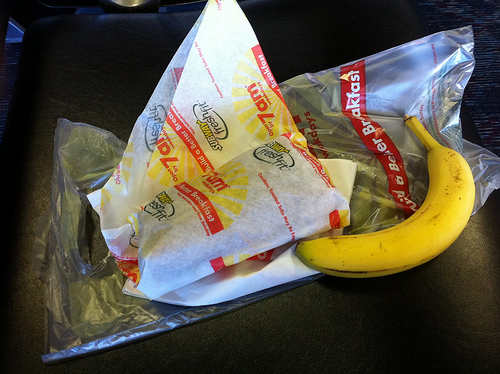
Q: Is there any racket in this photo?
A: No, there are no rackets.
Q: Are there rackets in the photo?
A: No, there are no rackets.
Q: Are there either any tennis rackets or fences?
A: No, there are no tennis rackets or fences.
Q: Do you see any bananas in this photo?
A: Yes, there is a banana.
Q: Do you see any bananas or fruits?
A: Yes, there is a banana.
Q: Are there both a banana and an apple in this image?
A: No, there is a banana but no apples.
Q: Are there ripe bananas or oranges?
A: Yes, there is a ripe banana.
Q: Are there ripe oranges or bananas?
A: Yes, there is a ripe banana.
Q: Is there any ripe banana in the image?
A: Yes, there is a ripe banana.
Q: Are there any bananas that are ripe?
A: Yes, there is a banana that is ripe.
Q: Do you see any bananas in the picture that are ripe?
A: Yes, there is a banana that is ripe.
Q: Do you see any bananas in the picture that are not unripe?
A: Yes, there is an ripe banana.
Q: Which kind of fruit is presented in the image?
A: The fruit is a banana.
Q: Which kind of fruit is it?
A: The fruit is a banana.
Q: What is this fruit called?
A: This is a banana.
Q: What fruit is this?
A: This is a banana.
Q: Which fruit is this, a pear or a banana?
A: This is a banana.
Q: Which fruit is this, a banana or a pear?
A: This is a banana.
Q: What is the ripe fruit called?
A: The fruit is a banana.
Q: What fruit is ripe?
A: The fruit is a banana.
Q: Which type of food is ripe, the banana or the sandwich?
A: The banana is ripe.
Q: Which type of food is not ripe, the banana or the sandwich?
A: The sandwich is not ripe.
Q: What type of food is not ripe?
A: The food is a sandwich.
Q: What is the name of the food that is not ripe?
A: The food is a sandwich.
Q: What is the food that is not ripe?
A: The food is a sandwich.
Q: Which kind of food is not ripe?
A: The food is a sandwich.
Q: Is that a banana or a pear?
A: That is a banana.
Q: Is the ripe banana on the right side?
A: Yes, the banana is on the right of the image.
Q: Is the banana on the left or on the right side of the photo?
A: The banana is on the right of the image.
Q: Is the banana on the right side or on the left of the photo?
A: The banana is on the right of the image.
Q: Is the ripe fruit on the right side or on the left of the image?
A: The banana is on the right of the image.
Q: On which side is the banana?
A: The banana is on the right of the image.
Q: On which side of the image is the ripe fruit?
A: The banana is on the right of the image.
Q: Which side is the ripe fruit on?
A: The banana is on the right of the image.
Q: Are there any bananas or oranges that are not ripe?
A: No, there is a banana but it is ripe.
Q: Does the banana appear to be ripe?
A: Yes, the banana is ripe.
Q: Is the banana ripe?
A: Yes, the banana is ripe.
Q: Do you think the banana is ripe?
A: Yes, the banana is ripe.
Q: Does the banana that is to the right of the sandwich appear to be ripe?
A: Yes, the banana is ripe.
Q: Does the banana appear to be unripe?
A: No, the banana is ripe.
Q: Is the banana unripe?
A: No, the banana is ripe.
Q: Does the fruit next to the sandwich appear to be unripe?
A: No, the banana is ripe.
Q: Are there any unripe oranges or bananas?
A: No, there is a banana but it is ripe.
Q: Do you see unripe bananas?
A: No, there is a banana but it is ripe.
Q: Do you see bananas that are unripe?
A: No, there is a banana but it is ripe.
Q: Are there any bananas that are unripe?
A: No, there is a banana but it is ripe.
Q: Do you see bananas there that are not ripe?
A: No, there is a banana but it is ripe.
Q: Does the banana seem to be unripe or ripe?
A: The banana is ripe.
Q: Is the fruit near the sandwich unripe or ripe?
A: The banana is ripe.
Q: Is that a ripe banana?
A: Yes, that is a ripe banana.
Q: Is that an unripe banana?
A: No, that is a ripe banana.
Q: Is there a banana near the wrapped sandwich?
A: Yes, there is a banana near the sandwich.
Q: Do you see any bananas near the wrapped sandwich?
A: Yes, there is a banana near the sandwich.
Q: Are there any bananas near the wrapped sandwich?
A: Yes, there is a banana near the sandwich.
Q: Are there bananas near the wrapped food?
A: Yes, there is a banana near the sandwich.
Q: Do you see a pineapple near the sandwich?
A: No, there is a banana near the sandwich.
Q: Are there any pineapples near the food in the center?
A: No, there is a banana near the sandwich.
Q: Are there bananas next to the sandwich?
A: Yes, there is a banana next to the sandwich.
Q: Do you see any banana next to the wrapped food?
A: Yes, there is a banana next to the sandwich.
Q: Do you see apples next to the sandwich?
A: No, there is a banana next to the sandwich.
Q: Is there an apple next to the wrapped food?
A: No, there is a banana next to the sandwich.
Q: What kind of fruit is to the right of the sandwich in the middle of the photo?
A: The fruit is a banana.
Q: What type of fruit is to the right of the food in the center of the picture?
A: The fruit is a banana.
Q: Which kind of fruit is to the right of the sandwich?
A: The fruit is a banana.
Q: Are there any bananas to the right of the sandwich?
A: Yes, there is a banana to the right of the sandwich.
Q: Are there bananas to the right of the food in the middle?
A: Yes, there is a banana to the right of the sandwich.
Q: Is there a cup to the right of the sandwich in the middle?
A: No, there is a banana to the right of the sandwich.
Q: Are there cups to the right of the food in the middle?
A: No, there is a banana to the right of the sandwich.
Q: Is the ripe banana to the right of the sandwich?
A: Yes, the banana is to the right of the sandwich.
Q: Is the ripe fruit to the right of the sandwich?
A: Yes, the banana is to the right of the sandwich.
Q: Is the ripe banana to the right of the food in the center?
A: Yes, the banana is to the right of the sandwich.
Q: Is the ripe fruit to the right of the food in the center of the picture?
A: Yes, the banana is to the right of the sandwich.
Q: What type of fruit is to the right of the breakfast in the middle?
A: The fruit is a banana.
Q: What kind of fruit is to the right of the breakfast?
A: The fruit is a banana.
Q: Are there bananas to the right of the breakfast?
A: Yes, there is a banana to the right of the breakfast.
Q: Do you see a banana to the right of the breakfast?
A: Yes, there is a banana to the right of the breakfast.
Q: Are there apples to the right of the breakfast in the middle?
A: No, there is a banana to the right of the breakfast.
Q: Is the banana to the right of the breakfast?
A: Yes, the banana is to the right of the breakfast.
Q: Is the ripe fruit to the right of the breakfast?
A: Yes, the banana is to the right of the breakfast.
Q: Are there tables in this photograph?
A: Yes, there is a table.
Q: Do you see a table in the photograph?
A: Yes, there is a table.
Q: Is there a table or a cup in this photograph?
A: Yes, there is a table.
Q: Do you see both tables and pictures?
A: No, there is a table but no pictures.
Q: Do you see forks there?
A: No, there are no forks.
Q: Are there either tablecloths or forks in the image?
A: No, there are no forks or tablecloths.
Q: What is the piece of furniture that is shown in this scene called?
A: The piece of furniture is a table.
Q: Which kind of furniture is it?
A: The piece of furniture is a table.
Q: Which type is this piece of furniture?
A: That is a table.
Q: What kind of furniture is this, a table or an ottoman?
A: That is a table.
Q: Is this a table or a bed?
A: This is a table.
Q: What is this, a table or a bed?
A: This is a table.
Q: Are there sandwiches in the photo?
A: Yes, there is a sandwich.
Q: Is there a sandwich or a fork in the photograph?
A: Yes, there is a sandwich.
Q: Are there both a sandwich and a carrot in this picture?
A: No, there is a sandwich but no carrots.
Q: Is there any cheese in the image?
A: No, there is no cheese.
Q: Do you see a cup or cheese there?
A: No, there are no cheese or cups.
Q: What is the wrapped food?
A: The food is a sandwich.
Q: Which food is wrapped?
A: The food is a sandwich.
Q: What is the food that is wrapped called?
A: The food is a sandwich.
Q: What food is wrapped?
A: The food is a sandwich.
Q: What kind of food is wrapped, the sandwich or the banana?
A: The sandwich is wrapped.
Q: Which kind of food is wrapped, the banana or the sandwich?
A: The sandwich is wrapped.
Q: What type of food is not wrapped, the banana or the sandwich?
A: The banana is not wrapped.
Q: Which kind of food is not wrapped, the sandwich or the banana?
A: The banana is not wrapped.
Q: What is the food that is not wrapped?
A: The food is a banana.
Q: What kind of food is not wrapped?
A: The food is a banana.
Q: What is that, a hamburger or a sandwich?
A: That is a sandwich.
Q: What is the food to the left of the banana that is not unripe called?
A: The food is a sandwich.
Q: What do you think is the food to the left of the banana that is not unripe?
A: The food is a sandwich.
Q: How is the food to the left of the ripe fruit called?
A: The food is a sandwich.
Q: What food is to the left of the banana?
A: The food is a sandwich.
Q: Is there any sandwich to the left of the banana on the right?
A: Yes, there is a sandwich to the left of the banana.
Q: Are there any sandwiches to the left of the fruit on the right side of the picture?
A: Yes, there is a sandwich to the left of the banana.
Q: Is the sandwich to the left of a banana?
A: Yes, the sandwich is to the left of a banana.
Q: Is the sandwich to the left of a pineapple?
A: No, the sandwich is to the left of a banana.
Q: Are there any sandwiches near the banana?
A: Yes, there is a sandwich near the banana.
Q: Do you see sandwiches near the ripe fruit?
A: Yes, there is a sandwich near the banana.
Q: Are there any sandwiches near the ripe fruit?
A: Yes, there is a sandwich near the banana.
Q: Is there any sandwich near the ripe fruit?
A: Yes, there is a sandwich near the banana.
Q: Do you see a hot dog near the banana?
A: No, there is a sandwich near the banana.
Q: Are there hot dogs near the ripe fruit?
A: No, there is a sandwich near the banana.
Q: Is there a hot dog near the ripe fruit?
A: No, there is a sandwich near the banana.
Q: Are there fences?
A: No, there are no fences.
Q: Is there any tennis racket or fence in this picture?
A: No, there are no fences or rackets.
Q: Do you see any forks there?
A: No, there are no forks.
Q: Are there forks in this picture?
A: No, there are no forks.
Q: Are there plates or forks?
A: No, there are no forks or plates.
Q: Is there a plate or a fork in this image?
A: No, there are no forks or plates.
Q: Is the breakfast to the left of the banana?
A: Yes, the breakfast is to the left of the banana.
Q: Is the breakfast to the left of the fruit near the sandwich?
A: Yes, the breakfast is to the left of the banana.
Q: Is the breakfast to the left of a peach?
A: No, the breakfast is to the left of the banana.